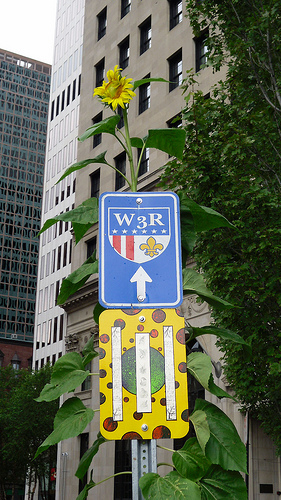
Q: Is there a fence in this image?
A: No, there are no fences.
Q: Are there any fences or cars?
A: No, there are no fences or cars.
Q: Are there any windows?
A: Yes, there is a window.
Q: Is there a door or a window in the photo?
A: Yes, there is a window.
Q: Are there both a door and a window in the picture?
A: Yes, there are both a window and a door.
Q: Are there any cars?
A: No, there are no cars.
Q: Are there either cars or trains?
A: No, there are no cars or trains.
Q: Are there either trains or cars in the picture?
A: No, there are no cars or trains.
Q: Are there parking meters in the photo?
A: No, there are no parking meters.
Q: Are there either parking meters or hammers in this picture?
A: No, there are no parking meters or hammers.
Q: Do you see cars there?
A: No, there are no cars.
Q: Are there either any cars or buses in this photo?
A: No, there are no cars or buses.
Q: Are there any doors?
A: Yes, there is a door.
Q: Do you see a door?
A: Yes, there is a door.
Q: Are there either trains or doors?
A: Yes, there is a door.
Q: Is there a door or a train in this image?
A: Yes, there is a door.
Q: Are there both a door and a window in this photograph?
A: Yes, there are both a door and a window.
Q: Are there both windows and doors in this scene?
A: Yes, there are both a door and a window.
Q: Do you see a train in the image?
A: No, there are no trains.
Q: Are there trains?
A: No, there are no trains.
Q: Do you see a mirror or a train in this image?
A: No, there are no trains or mirrors.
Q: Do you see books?
A: No, there are no books.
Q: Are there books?
A: No, there are no books.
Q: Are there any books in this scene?
A: No, there are no books.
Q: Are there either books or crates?
A: No, there are no books or crates.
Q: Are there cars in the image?
A: No, there are no cars.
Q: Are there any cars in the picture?
A: No, there are no cars.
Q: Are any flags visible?
A: Yes, there is a flag.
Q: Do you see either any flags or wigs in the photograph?
A: Yes, there is a flag.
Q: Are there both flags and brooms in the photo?
A: No, there is a flag but no brooms.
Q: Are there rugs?
A: No, there are no rugs.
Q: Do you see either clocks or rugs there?
A: No, there are no rugs or clocks.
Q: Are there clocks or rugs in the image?
A: No, there are no rugs or clocks.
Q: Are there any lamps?
A: No, there are no lamps.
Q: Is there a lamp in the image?
A: No, there are no lamps.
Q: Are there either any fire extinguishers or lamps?
A: No, there are no lamps or fire extinguishers.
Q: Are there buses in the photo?
A: No, there are no buses.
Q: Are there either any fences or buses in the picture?
A: No, there are no buses or fences.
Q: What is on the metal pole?
A: The sign is on the pole.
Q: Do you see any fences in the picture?
A: No, there are no fences.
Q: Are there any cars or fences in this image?
A: No, there are no fences or cars.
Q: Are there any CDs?
A: No, there are no cds.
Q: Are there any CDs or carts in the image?
A: No, there are no CDs or carts.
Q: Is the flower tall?
A: Yes, the flower is tall.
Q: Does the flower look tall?
A: Yes, the flower is tall.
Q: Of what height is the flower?
A: The flower is tall.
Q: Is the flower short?
A: No, the flower is tall.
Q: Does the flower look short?
A: No, the flower is tall.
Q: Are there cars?
A: No, there are no cars.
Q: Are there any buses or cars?
A: No, there are no cars or buses.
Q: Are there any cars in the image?
A: No, there are no cars.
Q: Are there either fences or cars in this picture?
A: No, there are no cars or fences.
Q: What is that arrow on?
A: The arrow is on the sign.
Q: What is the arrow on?
A: The arrow is on the sign.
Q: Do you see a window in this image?
A: Yes, there is a window.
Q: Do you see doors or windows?
A: Yes, there is a window.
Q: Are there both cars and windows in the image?
A: No, there is a window but no cars.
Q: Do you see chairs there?
A: No, there are no chairs.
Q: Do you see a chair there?
A: No, there are no chairs.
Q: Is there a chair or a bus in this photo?
A: No, there are no chairs or buses.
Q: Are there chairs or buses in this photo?
A: No, there are no chairs or buses.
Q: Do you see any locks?
A: No, there are no locks.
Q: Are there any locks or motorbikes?
A: No, there are no locks or motorbikes.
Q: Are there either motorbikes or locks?
A: No, there are no locks or motorbikes.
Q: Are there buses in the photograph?
A: No, there are no buses.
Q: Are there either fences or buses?
A: No, there are no buses or fences.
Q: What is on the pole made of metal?
A: The sign is on the pole.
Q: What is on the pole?
A: The sign is on the pole.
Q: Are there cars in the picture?
A: No, there are no cars.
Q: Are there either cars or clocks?
A: No, there are no cars or clocks.